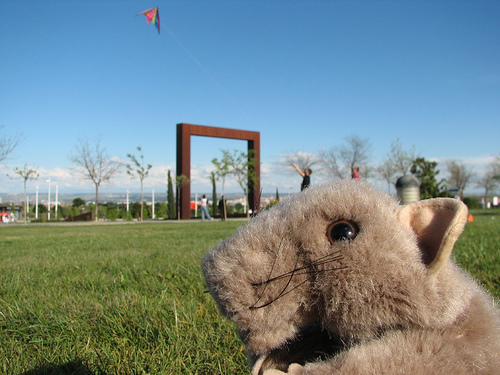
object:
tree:
[167, 169, 175, 218]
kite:
[136, 6, 161, 34]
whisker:
[252, 251, 342, 286]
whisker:
[251, 256, 300, 309]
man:
[293, 163, 312, 191]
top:
[301, 176, 310, 191]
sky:
[0, 0, 499, 195]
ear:
[397, 196, 468, 272]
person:
[200, 194, 213, 220]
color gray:
[369, 233, 413, 273]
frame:
[175, 122, 260, 219]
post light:
[45, 178, 50, 221]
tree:
[7, 162, 40, 218]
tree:
[475, 172, 497, 211]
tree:
[377, 160, 399, 190]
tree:
[212, 148, 256, 195]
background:
[0, 1, 499, 220]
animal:
[200, 179, 499, 374]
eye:
[326, 219, 360, 245]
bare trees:
[74, 143, 123, 221]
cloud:
[24, 162, 173, 186]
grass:
[0, 214, 499, 374]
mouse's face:
[201, 183, 421, 354]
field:
[0, 213, 499, 375]